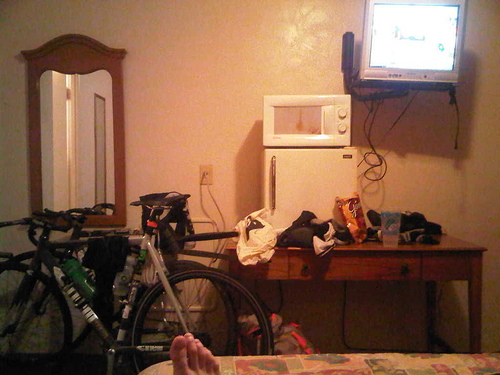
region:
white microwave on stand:
[259, 98, 354, 155]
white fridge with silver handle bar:
[245, 156, 379, 250]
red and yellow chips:
[331, 175, 380, 253]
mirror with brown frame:
[19, 41, 155, 234]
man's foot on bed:
[166, 324, 228, 368]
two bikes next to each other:
[42, 215, 290, 359]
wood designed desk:
[216, 226, 498, 290]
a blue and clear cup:
[372, 199, 426, 279]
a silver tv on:
[357, 11, 474, 90]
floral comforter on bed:
[288, 359, 478, 373]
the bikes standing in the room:
[12, 200, 274, 370]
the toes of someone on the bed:
[168, 332, 223, 374]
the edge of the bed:
[136, 337, 486, 374]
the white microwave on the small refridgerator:
[256, 94, 353, 146]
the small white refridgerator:
[256, 149, 366, 233]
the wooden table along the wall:
[222, 220, 485, 365]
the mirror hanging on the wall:
[18, 32, 135, 224]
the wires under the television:
[355, 93, 464, 189]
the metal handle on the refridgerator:
[268, 153, 280, 215]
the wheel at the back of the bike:
[131, 268, 275, 374]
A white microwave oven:
[263, 92, 352, 147]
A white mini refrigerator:
[263, 148, 356, 238]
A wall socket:
[197, 162, 213, 186]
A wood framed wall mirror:
[18, 32, 129, 227]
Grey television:
[360, 2, 465, 86]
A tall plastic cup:
[378, 200, 401, 250]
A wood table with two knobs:
[226, 222, 491, 352]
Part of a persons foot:
[168, 330, 220, 373]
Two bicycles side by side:
[3, 193, 271, 374]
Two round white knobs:
[336, 103, 348, 136]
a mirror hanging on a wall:
[15, 25, 125, 224]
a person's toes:
[173, 329, 235, 374]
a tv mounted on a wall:
[333, 2, 474, 123]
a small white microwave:
[248, 87, 353, 147]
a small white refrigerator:
[246, 138, 361, 230]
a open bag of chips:
[323, 181, 370, 245]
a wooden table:
[203, 214, 481, 330]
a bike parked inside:
[0, 184, 204, 358]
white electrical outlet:
[192, 151, 224, 209]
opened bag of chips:
[329, 174, 376, 247]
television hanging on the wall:
[350, 6, 478, 109]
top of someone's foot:
[162, 328, 228, 374]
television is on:
[357, 0, 467, 95]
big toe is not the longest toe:
[169, 328, 226, 373]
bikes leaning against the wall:
[3, 183, 278, 374]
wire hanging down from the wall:
[197, 181, 232, 313]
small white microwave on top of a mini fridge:
[262, 91, 377, 231]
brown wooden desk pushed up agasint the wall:
[225, 228, 499, 363]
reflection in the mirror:
[32, 64, 126, 212]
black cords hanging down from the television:
[349, 81, 406, 189]